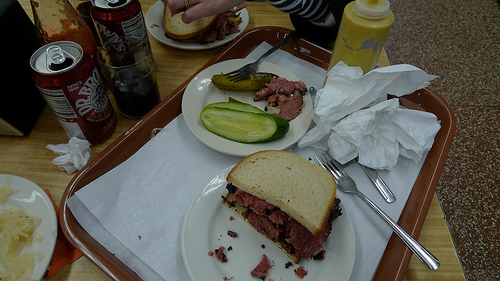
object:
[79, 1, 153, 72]
can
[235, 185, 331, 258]
meat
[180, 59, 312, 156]
plate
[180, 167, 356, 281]
plate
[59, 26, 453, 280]
tray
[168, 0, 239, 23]
hand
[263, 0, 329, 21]
arm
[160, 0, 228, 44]
sandwich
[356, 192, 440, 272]
handle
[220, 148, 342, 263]
sandwich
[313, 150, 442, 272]
fork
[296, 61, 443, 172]
napkin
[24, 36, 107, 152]
soda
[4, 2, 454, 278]
table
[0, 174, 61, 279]
plate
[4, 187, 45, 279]
food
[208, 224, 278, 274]
crambs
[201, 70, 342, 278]
dishes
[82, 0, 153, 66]
drink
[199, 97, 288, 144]
pickle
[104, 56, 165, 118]
glass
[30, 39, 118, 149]
coke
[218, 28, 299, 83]
fork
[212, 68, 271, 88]
pickle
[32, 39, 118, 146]
bottle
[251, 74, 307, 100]
corned beef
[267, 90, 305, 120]
corned beef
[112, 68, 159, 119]
beverage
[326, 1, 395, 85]
bottle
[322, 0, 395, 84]
mustard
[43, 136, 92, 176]
napkin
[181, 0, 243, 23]
finger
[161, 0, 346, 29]
human being